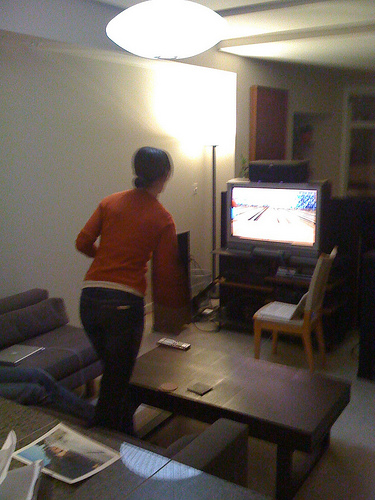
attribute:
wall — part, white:
[4, 36, 240, 282]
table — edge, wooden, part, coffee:
[145, 323, 369, 460]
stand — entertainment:
[270, 447, 324, 499]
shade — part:
[194, 111, 235, 153]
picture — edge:
[22, 426, 102, 481]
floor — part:
[148, 312, 371, 494]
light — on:
[108, 5, 220, 57]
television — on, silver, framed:
[223, 183, 321, 262]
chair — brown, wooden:
[255, 254, 344, 369]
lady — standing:
[71, 151, 183, 400]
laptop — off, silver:
[4, 341, 43, 369]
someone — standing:
[294, 118, 317, 176]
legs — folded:
[242, 430, 365, 491]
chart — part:
[246, 89, 290, 155]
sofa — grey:
[0, 296, 82, 381]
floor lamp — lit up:
[191, 118, 226, 315]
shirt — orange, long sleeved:
[92, 192, 171, 292]